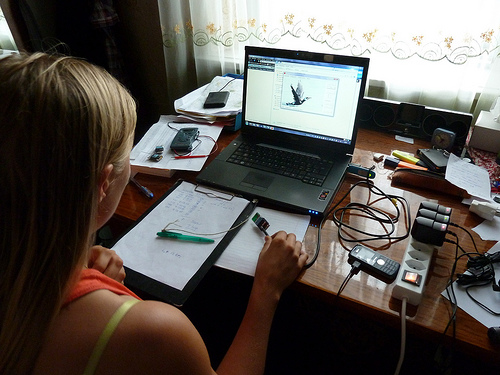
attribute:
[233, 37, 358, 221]
laptop — black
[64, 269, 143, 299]
shirt — orange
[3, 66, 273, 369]
girl — young, blonde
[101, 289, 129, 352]
strap — yellow, green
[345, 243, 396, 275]
cellphone — charging, small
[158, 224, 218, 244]
pen — green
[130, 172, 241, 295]
clip board — black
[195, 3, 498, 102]
curtain — white, floral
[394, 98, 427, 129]
station — docking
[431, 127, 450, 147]
clock — small, blue, alarm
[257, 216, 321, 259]
cord — electrical, extension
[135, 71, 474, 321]
table — brown, wooden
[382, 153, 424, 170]
marker — orange, yellow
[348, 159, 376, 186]
plug — usb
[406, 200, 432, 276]
plug — multi outlet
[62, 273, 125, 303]
top — orange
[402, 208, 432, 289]
outlet — electric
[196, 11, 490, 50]
flowers — yellow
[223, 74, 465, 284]
electronics — together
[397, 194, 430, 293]
powerstrip — red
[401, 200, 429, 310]
surge protector — white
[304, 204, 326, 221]
lights — blue